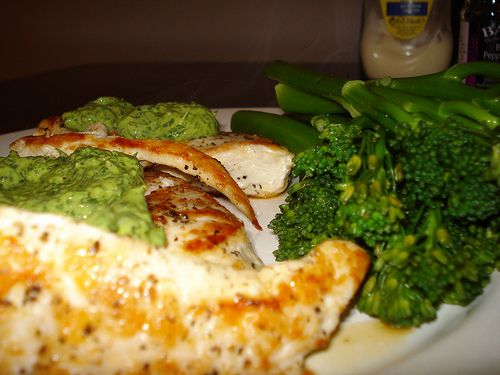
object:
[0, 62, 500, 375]
food